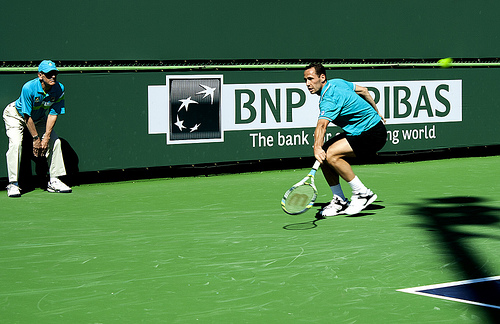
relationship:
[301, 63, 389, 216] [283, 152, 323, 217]
man holding tennis racket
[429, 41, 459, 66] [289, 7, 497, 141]
ball flying through air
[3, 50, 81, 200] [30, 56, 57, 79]
man in hat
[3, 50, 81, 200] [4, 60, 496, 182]
man leaning against wall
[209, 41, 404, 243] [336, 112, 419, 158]
man wears shorts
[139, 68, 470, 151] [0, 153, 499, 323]
wall sign on court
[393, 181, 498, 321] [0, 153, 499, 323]
shadow on court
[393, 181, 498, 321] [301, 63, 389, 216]
shadow behind man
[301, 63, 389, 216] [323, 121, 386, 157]
man wearing shorts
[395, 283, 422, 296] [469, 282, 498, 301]
lines on court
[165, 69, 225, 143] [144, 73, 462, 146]
bank symbol on wall sign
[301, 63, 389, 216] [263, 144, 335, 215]
man holding tennis racket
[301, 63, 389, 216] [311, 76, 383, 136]
man in shirt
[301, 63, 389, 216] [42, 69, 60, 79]
man with black shades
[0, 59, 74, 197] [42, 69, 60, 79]
man with black shades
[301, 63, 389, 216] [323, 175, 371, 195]
man wearing socks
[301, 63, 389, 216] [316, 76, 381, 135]
man wearing shirt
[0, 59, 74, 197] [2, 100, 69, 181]
man wearing pants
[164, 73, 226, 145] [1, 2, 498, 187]
bank symbol on wall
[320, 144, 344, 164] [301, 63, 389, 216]
knees of man